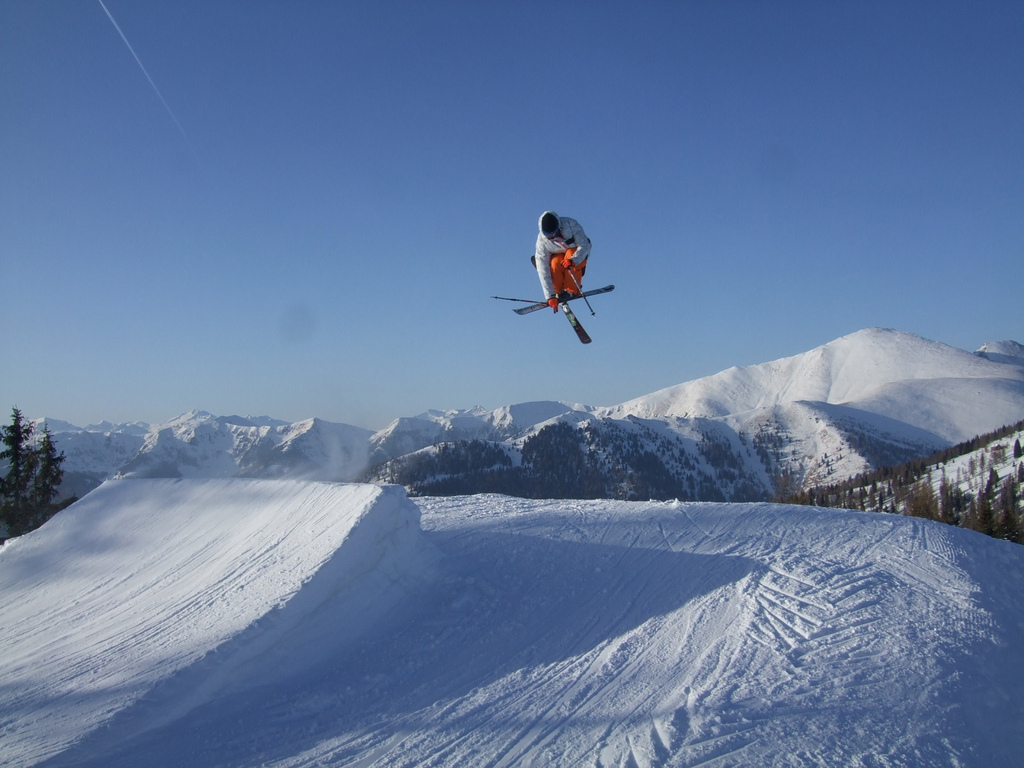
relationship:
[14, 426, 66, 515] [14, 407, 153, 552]
tree in woods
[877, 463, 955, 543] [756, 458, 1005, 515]
tree in woods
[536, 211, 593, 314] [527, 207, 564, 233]
man wears hood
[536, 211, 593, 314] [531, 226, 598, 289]
man wears sweater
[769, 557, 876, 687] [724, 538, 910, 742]
tracks on snow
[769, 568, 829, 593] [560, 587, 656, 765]
tracks on snow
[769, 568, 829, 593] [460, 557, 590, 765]
tracks on snow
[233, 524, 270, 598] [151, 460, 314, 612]
tracks on snow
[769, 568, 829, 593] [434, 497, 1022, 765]
tracks on snow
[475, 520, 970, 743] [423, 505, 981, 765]
snow on ground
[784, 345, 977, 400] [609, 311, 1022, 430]
snow on mountain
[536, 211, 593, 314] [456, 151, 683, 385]
man in air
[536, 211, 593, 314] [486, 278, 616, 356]
man wears skis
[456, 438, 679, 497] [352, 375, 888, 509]
trees ib hillside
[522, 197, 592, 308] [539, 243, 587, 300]
man wearing pants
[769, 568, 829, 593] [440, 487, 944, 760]
tracks in snow